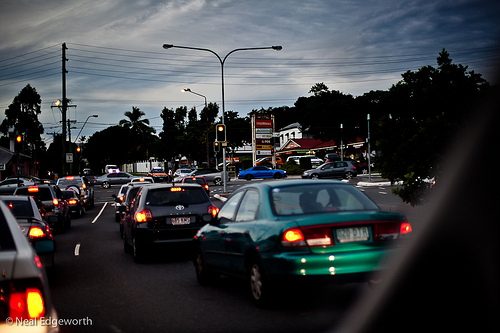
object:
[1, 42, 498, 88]
wires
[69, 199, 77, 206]
taillight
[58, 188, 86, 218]
car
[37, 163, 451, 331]
street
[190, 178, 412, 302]
car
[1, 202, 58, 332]
car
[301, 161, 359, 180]
car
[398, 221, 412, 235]
lights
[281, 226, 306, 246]
lights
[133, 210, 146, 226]
lights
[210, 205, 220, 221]
lights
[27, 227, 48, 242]
lights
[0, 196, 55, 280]
car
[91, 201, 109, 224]
white line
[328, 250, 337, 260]
light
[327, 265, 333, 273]
light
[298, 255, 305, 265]
light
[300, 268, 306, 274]
light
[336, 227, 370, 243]
license plate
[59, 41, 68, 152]
pole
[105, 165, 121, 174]
suv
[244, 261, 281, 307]
tire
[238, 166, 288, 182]
car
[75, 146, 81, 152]
light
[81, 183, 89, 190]
tail light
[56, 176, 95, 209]
car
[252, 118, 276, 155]
signs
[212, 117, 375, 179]
shopping center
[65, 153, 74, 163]
signs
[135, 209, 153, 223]
taillight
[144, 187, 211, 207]
window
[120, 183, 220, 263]
car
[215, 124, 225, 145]
street light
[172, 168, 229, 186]
cars